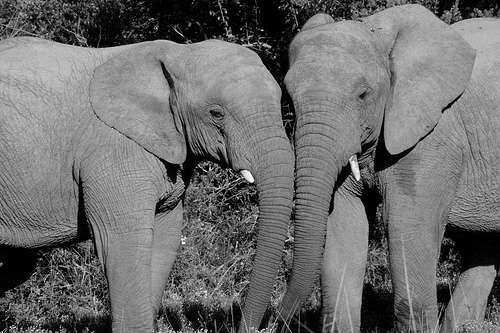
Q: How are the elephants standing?
A: Facing each other.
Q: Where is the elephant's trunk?
A: In the front of his face.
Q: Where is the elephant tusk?
A: On the side of the trunk.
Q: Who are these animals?
A: Elephants.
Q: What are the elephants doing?
A: Standing.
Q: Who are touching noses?
A: The elephants.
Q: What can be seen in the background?
A: Trees.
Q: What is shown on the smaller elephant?
A: Smaller front legs.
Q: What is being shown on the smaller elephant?
A: The trunk.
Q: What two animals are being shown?
A: Elephants.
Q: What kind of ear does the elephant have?
A: Big and floppy.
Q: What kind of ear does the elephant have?
A: Big and floppy.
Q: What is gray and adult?
A: Elephants.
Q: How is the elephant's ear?
A: It is gray.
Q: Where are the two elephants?
A: They are standing next to each other.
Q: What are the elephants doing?
A: The are looking at each other.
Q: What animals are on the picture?
A: Elephants.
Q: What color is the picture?
A: Black and white.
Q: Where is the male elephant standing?
A: On the right.